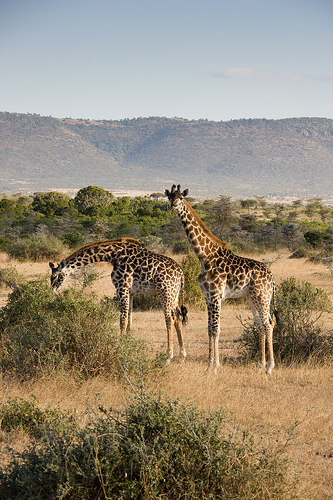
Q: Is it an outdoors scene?
A: Yes, it is outdoors.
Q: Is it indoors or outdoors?
A: It is outdoors.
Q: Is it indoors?
A: No, it is outdoors.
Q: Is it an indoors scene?
A: No, it is outdoors.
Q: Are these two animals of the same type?
A: Yes, all the animals are giraffes.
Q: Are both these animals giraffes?
A: Yes, all the animals are giraffes.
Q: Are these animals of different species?
A: No, all the animals are giraffes.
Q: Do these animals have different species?
A: No, all the animals are giraffes.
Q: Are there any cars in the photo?
A: No, there are no cars.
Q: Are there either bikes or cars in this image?
A: No, there are no cars or bikes.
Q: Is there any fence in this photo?
A: No, there are no fences.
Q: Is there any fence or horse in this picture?
A: No, there are no fences or horses.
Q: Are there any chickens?
A: No, there are no chickens.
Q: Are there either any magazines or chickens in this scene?
A: No, there are no chickens or magazines.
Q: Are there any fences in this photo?
A: No, there are no fences.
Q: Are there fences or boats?
A: No, there are no fences or boats.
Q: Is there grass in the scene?
A: Yes, there is grass.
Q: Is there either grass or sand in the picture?
A: Yes, there is grass.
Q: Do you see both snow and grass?
A: No, there is grass but no snow.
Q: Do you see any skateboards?
A: No, there are no skateboards.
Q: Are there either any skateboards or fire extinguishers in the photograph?
A: No, there are no skateboards or fire extinguishers.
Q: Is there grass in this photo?
A: Yes, there is grass.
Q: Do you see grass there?
A: Yes, there is grass.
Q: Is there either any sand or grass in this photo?
A: Yes, there is grass.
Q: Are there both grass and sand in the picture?
A: No, there is grass but no sand.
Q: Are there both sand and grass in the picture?
A: No, there is grass but no sand.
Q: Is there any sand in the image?
A: No, there is no sand.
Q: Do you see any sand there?
A: No, there is no sand.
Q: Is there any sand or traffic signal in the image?
A: No, there are no sand or traffic lights.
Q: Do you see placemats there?
A: No, there are no placemats.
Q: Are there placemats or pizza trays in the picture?
A: No, there are no placemats or pizza trays.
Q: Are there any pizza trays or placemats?
A: No, there are no placemats or pizza trays.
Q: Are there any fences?
A: No, there are no fences.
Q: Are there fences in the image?
A: No, there are no fences.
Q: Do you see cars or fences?
A: No, there are no fences or cars.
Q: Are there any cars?
A: No, there are no cars.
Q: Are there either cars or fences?
A: No, there are no cars or fences.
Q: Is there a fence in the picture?
A: No, there are no fences.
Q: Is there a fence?
A: No, there are no fences.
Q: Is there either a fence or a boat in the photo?
A: No, there are no fences or boats.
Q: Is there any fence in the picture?
A: No, there are no fences.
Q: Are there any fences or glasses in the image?
A: No, there are no fences or glasses.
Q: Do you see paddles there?
A: No, there are no paddles.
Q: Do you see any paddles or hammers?
A: No, there are no paddles or hammers.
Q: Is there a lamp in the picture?
A: No, there are no lamps.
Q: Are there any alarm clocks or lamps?
A: No, there are no lamps or alarm clocks.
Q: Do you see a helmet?
A: No, there are no helmets.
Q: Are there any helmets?
A: No, there are no helmets.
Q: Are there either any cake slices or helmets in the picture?
A: No, there are no helmets or cake slices.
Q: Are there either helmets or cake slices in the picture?
A: No, there are no helmets or cake slices.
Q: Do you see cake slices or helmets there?
A: No, there are no helmets or cake slices.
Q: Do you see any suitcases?
A: No, there are no suitcases.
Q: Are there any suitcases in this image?
A: No, there are no suitcases.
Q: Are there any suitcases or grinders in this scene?
A: No, there are no suitcases or grinders.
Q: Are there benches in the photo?
A: No, there are no benches.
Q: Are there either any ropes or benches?
A: No, there are no benches or ropes.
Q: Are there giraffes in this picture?
A: Yes, there is a giraffe.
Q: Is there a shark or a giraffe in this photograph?
A: Yes, there is a giraffe.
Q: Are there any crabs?
A: No, there are no crabs.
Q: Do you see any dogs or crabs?
A: No, there are no crabs or dogs.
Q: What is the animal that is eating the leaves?
A: The animal is a giraffe.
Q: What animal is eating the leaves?
A: The animal is a giraffe.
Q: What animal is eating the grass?
A: The giraffe is eating the grass.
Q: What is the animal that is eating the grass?
A: The animal is a giraffe.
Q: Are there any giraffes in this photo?
A: Yes, there is a giraffe.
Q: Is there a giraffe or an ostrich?
A: Yes, there is a giraffe.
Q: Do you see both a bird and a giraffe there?
A: No, there is a giraffe but no birds.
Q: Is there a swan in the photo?
A: No, there are no swans.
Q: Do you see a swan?
A: No, there are no swans.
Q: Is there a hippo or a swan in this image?
A: No, there are no swans or hippoes.